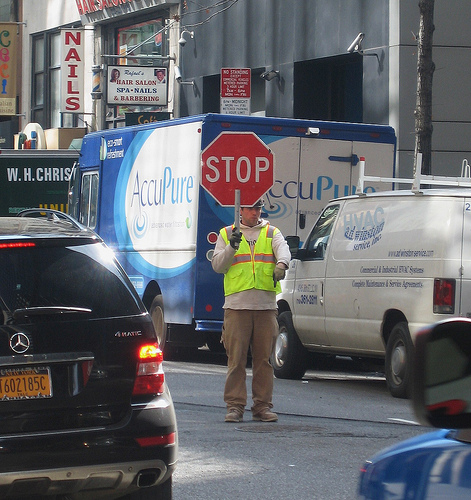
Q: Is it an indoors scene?
A: Yes, it is indoors.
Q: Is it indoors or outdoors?
A: It is indoors.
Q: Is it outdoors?
A: No, it is indoors.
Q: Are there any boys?
A: No, there are no boys.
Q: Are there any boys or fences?
A: No, there are no boys or fences.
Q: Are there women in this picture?
A: No, there are no women.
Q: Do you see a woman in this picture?
A: No, there are no women.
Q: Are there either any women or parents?
A: No, there are no women or parents.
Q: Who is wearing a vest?
A: The man is wearing a vest.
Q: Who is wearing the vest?
A: The man is wearing a vest.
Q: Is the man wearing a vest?
A: Yes, the man is wearing a vest.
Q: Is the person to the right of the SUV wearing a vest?
A: Yes, the man is wearing a vest.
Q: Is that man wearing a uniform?
A: No, the man is wearing a vest.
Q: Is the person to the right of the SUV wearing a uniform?
A: No, the man is wearing a vest.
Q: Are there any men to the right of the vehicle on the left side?
A: Yes, there is a man to the right of the SUV.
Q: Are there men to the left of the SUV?
A: No, the man is to the right of the SUV.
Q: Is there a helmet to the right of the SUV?
A: No, there is a man to the right of the SUV.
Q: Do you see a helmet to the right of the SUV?
A: No, there is a man to the right of the SUV.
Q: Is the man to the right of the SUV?
A: Yes, the man is to the right of the SUV.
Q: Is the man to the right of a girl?
A: No, the man is to the right of the SUV.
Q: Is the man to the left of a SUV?
A: No, the man is to the right of a SUV.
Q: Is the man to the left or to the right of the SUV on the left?
A: The man is to the right of the SUV.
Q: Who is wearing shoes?
A: The man is wearing shoes.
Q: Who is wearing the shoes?
A: The man is wearing shoes.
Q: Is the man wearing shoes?
A: Yes, the man is wearing shoes.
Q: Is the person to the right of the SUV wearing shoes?
A: Yes, the man is wearing shoes.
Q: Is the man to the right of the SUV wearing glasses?
A: No, the man is wearing shoes.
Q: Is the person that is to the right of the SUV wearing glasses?
A: No, the man is wearing shoes.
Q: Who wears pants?
A: The man wears pants.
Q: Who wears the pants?
A: The man wears pants.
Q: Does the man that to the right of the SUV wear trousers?
A: Yes, the man wears trousers.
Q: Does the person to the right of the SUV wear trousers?
A: Yes, the man wears trousers.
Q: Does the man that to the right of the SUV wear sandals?
A: No, the man wears trousers.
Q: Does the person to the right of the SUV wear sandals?
A: No, the man wears trousers.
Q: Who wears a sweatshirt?
A: The man wears a sweatshirt.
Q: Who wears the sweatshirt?
A: The man wears a sweatshirt.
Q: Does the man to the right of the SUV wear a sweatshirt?
A: Yes, the man wears a sweatshirt.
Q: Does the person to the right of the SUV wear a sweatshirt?
A: Yes, the man wears a sweatshirt.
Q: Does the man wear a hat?
A: No, the man wears a sweatshirt.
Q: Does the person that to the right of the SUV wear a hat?
A: No, the man wears a sweatshirt.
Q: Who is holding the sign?
A: The man is holding the sign.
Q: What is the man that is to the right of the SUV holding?
A: The man is holding the sign.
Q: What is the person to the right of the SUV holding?
A: The man is holding the sign.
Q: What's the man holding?
A: The man is holding the sign.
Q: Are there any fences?
A: No, there are no fences.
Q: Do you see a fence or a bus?
A: No, there are no fences or buses.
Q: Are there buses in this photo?
A: No, there are no buses.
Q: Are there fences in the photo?
A: No, there are no fences.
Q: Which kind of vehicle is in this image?
A: The vehicle is a SUV.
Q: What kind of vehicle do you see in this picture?
A: The vehicle is a SUV.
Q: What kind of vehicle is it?
A: The vehicle is a SUV.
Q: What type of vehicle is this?
A: That is a SUV.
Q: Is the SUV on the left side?
A: Yes, the SUV is on the left of the image.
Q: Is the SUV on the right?
A: No, the SUV is on the left of the image.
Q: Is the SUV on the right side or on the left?
A: The SUV is on the left of the image.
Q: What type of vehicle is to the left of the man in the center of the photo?
A: The vehicle is a SUV.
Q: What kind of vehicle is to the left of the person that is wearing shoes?
A: The vehicle is a SUV.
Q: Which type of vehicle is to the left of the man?
A: The vehicle is a SUV.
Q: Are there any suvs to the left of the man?
A: Yes, there is a SUV to the left of the man.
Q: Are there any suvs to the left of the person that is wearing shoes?
A: Yes, there is a SUV to the left of the man.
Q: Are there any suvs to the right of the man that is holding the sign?
A: No, the SUV is to the left of the man.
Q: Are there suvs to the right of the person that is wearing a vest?
A: No, the SUV is to the left of the man.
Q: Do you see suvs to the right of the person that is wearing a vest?
A: No, the SUV is to the left of the man.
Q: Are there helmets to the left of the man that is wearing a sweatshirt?
A: No, there is a SUV to the left of the man.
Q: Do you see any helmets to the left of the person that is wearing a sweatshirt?
A: No, there is a SUV to the left of the man.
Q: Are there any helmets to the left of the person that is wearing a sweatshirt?
A: No, there is a SUV to the left of the man.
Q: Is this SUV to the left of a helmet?
A: No, the SUV is to the left of a man.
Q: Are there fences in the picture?
A: No, there are no fences.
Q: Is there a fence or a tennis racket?
A: No, there are no fences or rackets.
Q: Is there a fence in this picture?
A: No, there are no fences.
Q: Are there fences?
A: No, there are no fences.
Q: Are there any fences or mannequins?
A: No, there are no fences or mannequins.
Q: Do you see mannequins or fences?
A: No, there are no fences or mannequins.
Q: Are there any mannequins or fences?
A: No, there are no fences or mannequins.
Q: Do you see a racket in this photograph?
A: No, there are no rackets.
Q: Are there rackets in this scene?
A: No, there are no rackets.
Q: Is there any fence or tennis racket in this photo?
A: No, there are no rackets or fences.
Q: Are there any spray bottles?
A: No, there are no spray bottles.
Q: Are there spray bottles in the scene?
A: No, there are no spray bottles.